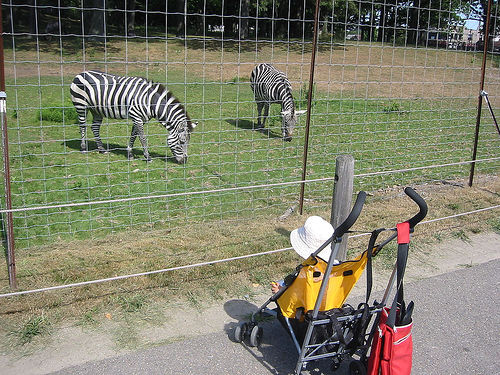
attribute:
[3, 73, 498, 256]
grass — green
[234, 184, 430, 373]
stroller — yellow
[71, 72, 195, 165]
zebra — eating, white, black, enclosed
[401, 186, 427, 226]
handle — black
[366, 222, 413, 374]
bag — hanging, red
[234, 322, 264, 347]
wheel — black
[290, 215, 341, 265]
hat — white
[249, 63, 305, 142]
zebra — eating, grazing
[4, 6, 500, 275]
fence — made of wire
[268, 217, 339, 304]
child — watching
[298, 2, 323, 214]
post — wooden, wood, metal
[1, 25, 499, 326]
grass — green